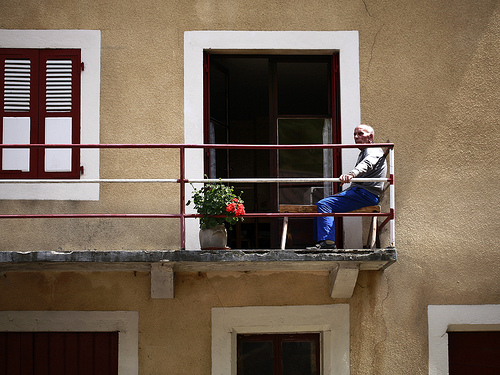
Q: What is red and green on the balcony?
A: Plant.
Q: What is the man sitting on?
A: Bench.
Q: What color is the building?
A: Tan.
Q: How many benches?
A: One.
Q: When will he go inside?
A: No indication.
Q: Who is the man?
A: No indication.